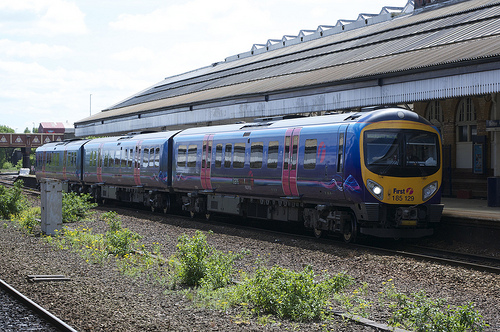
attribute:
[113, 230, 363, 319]
bushes — in the picture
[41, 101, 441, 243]
train — in the picture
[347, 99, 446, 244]
train — yellow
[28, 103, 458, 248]
passenger train — blue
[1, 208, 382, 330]
gravel — between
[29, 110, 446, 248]
blue train — in the picture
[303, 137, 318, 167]
window — in the picture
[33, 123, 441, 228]
train — in the picture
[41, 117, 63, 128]
rooftop — behind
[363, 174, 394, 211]
headlight — yellow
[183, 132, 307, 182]
train car — in the picture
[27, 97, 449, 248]
train — in the picture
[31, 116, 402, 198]
train — in the picture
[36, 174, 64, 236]
box — electrical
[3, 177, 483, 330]
weeds — in the picture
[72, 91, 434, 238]
train — in the picture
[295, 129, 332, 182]
window — in the picture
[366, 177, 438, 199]
headlights — in the picture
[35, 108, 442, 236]
train — in the picture